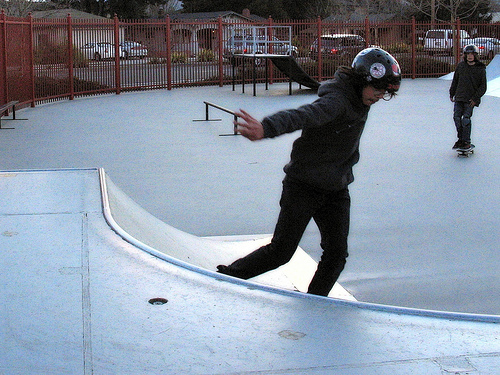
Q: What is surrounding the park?
A: A red fence.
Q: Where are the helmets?
A: On the heads of the skateboarders.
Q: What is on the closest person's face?
A: Glasses.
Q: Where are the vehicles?
A: On the other side of the red fence.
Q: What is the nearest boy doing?
A: Skateboarding down a ramp.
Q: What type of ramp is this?
A: Lifted.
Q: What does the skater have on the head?
A: A helmet.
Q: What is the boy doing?
A: Skateboarding.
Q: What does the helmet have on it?
A: Stickers.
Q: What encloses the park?
A: A fence.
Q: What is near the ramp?
A: The rails.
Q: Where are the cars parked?
A: At the houses.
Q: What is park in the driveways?
A: Cars.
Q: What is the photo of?
A: A skate park.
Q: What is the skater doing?
A: Going down the ramp.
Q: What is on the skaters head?
A: Helmets.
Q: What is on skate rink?
A: Ice.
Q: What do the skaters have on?
A: Coats.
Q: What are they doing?
A: Skateboarding.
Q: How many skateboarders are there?
A: Two.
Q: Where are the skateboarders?
A: AT skatepark.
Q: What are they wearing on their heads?
A: Helmets.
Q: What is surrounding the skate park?
A: A fence.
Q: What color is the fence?
A: Red.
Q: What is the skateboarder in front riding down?
A: A ramp.